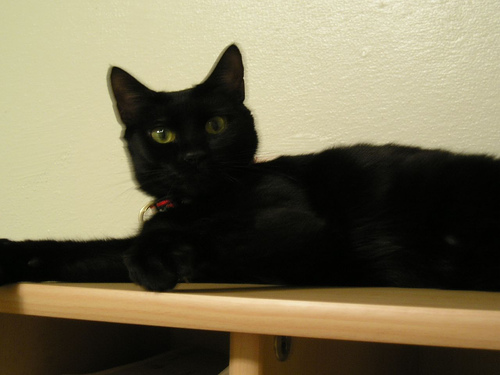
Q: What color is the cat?
A: Black.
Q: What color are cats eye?
A: Yellow.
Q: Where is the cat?
A: The shelf.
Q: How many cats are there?
A: One.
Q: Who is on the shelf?
A: The cat.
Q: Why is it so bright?
A: Lights are on.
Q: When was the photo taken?
A: Day time.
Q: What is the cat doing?
A: Laying.